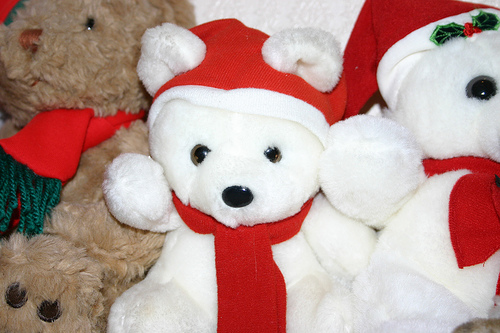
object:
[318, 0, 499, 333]
toy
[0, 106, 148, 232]
scarf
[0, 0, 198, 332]
bear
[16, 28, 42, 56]
nose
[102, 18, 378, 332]
middle bear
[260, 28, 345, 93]
ears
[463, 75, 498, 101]
eye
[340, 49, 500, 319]
stuffed animal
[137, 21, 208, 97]
ear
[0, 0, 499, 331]
teddy bar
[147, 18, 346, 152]
hat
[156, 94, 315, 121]
rim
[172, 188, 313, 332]
scarf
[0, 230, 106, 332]
foot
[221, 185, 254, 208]
nose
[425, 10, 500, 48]
mistle toe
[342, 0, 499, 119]
hat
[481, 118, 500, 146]
nose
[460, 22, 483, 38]
ribbon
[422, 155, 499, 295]
shawl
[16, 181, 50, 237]
marvin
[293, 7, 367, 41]
pocket